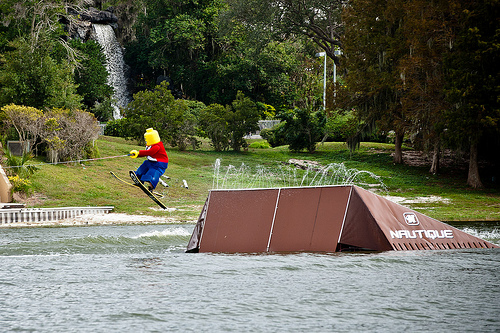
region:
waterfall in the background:
[85, 13, 149, 126]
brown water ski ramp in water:
[188, 182, 499, 260]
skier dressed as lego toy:
[103, 126, 182, 217]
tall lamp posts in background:
[315, 42, 348, 132]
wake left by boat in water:
[7, 223, 191, 265]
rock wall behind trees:
[378, 145, 478, 179]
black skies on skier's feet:
[106, 166, 176, 212]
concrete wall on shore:
[2, 205, 121, 232]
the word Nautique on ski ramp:
[380, 213, 470, 249]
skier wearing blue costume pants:
[120, 121, 179, 210]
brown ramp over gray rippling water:
[5, 186, 490, 326]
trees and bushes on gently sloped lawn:
[1, 101, 491, 213]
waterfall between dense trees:
[2, 0, 302, 115]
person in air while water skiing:
[0, 125, 170, 210]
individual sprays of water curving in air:
[202, 150, 382, 190]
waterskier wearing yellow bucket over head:
[125, 120, 166, 190]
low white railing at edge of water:
[0, 200, 115, 225]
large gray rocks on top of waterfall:
[66, 2, 117, 39]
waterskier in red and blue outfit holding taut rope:
[0, 126, 170, 191]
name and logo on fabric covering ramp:
[182, 185, 494, 251]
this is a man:
[75, 113, 286, 328]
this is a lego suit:
[130, 71, 227, 233]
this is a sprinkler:
[190, 143, 304, 188]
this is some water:
[150, 236, 256, 332]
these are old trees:
[300, 68, 470, 200]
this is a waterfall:
[108, 35, 142, 147]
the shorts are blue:
[82, 158, 204, 188]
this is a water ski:
[120, 136, 194, 243]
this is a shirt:
[133, 132, 190, 180]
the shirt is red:
[105, 121, 196, 174]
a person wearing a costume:
[113, 107, 178, 229]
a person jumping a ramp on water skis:
[87, 94, 197, 234]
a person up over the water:
[81, 101, 198, 248]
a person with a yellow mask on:
[130, 117, 172, 157]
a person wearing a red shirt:
[149, 134, 176, 164]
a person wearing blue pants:
[129, 148, 169, 186]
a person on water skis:
[110, 111, 176, 255]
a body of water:
[82, 269, 454, 329]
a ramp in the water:
[176, 156, 479, 303]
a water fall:
[82, 13, 137, 145]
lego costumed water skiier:
[103, 109, 187, 219]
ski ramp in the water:
[181, 184, 493, 279]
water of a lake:
[58, 263, 415, 320]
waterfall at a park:
[85, 18, 144, 125]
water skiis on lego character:
[115, 163, 175, 218]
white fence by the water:
[3, 199, 128, 229]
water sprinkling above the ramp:
[211, 155, 376, 192]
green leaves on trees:
[373, 21, 478, 109]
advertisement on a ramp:
[383, 209, 459, 247]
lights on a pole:
[311, 43, 333, 113]